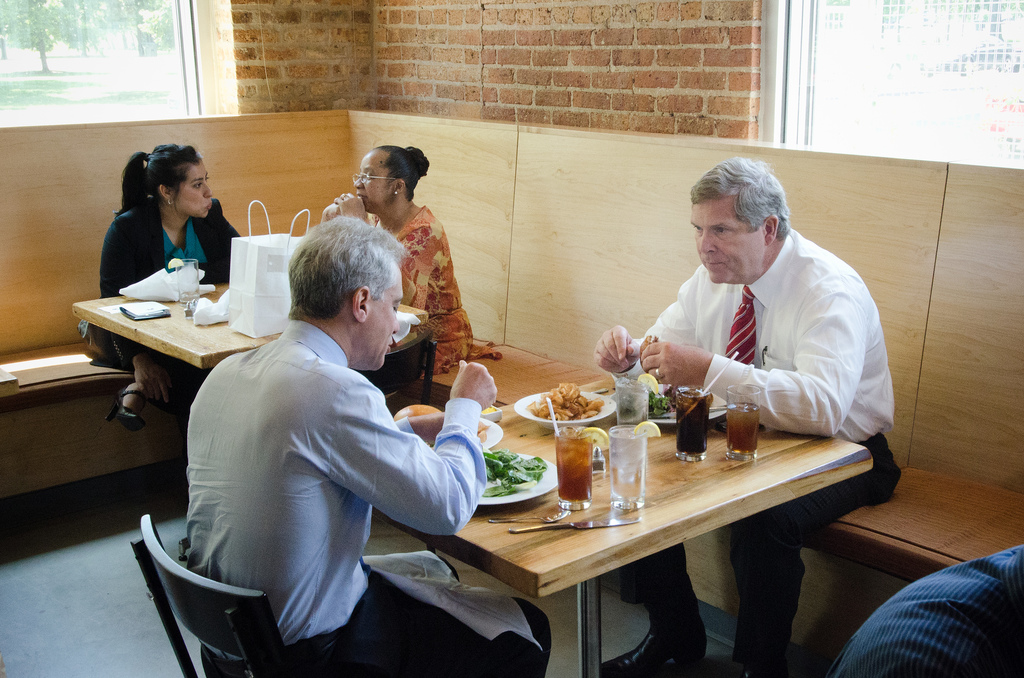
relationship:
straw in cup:
[522, 353, 594, 442] [533, 420, 611, 537]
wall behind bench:
[444, 16, 838, 161] [520, 102, 989, 465]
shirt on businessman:
[682, 275, 912, 425] [570, 156, 994, 502]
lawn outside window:
[29, 76, 75, 107] [40, 29, 140, 114]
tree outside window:
[7, 10, 55, 67] [40, 29, 140, 114]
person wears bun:
[317, 130, 443, 232] [385, 145, 438, 195]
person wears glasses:
[317, 130, 443, 232] [347, 180, 393, 196]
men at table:
[223, 247, 882, 516] [511, 461, 686, 522]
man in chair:
[183, 241, 451, 602] [103, 539, 302, 660]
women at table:
[105, 143, 447, 208] [90, 255, 218, 338]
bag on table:
[221, 212, 284, 312] [100, 282, 219, 375]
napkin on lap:
[386, 569, 505, 650] [360, 586, 456, 662]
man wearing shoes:
[649, 169, 878, 420] [634, 634, 723, 674]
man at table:
[708, 176, 823, 462] [602, 454, 704, 500]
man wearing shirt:
[625, 176, 907, 466] [720, 295, 928, 416]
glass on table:
[608, 417, 675, 551] [692, 480, 772, 519]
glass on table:
[535, 418, 594, 527] [522, 405, 561, 587]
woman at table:
[64, 124, 240, 284] [167, 292, 230, 360]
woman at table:
[345, 148, 436, 229] [107, 292, 229, 364]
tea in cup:
[558, 428, 590, 502] [554, 426, 595, 512]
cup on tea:
[554, 426, 595, 512] [558, 428, 590, 502]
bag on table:
[227, 198, 314, 349] [68, 269, 437, 370]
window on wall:
[6, 5, 232, 125] [5, 7, 524, 178]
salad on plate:
[492, 453, 545, 485] [477, 441, 558, 516]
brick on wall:
[553, 30, 653, 82] [452, 38, 660, 108]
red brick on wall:
[613, 86, 676, 115] [374, 4, 764, 130]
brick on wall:
[258, 38, 306, 69] [230, 3, 749, 144]